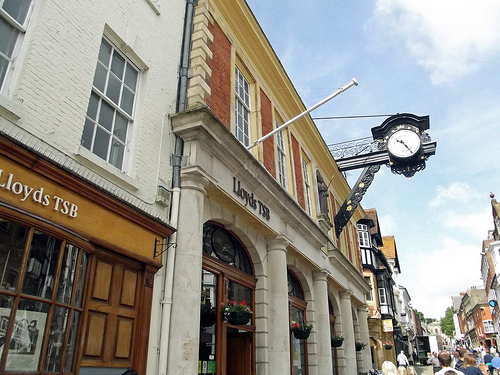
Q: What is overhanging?
A: A clock.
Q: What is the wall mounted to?
A: The building.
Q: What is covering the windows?
A: Panes.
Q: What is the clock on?
A: A beam.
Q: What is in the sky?
A: Clouds.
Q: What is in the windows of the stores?
A: Posters.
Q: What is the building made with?
A: Bricks.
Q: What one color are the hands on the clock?
A: Black.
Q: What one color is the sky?
A: Blue.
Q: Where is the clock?
A: Side of the building.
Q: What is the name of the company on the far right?
A: Lloyds tsb.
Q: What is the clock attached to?
A: Lloyds tsb company building.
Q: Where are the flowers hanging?
A: Outside of storefront windows.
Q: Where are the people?
A: Street.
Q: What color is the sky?
A: Blue.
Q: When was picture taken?
A: Daytime.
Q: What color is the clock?
A: Black.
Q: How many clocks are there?
A: One.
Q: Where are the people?
A: Under the clock.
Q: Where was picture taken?
A: In a city.